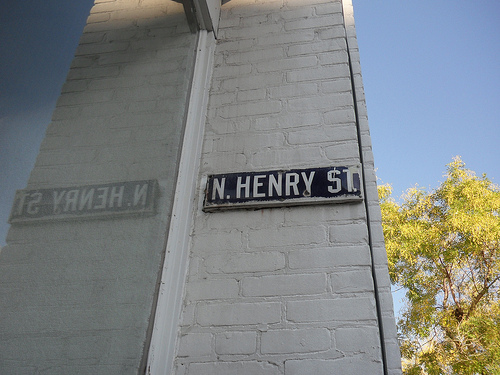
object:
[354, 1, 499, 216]
sky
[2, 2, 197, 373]
window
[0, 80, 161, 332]
reflection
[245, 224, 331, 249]
brick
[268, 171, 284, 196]
letters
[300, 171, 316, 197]
letters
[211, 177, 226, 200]
letters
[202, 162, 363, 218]
sign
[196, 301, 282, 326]
brick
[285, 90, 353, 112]
brick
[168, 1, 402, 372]
column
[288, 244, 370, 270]
brick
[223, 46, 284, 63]
brick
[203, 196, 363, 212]
paint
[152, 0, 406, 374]
wall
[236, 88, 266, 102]
brick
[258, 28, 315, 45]
brick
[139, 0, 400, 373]
building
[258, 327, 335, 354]
white brick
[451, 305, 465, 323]
nest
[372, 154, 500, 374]
tree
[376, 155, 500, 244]
tree top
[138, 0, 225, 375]
window frame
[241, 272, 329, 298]
brick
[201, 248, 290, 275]
brick